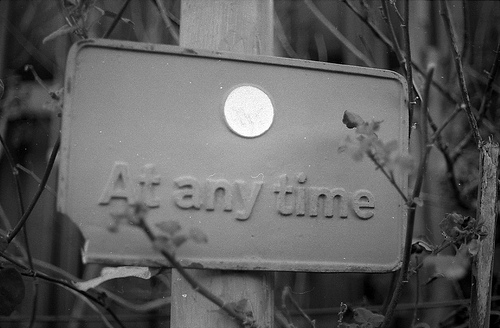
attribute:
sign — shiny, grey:
[62, 45, 448, 291]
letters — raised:
[107, 169, 422, 229]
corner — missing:
[53, 209, 88, 264]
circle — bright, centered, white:
[220, 84, 285, 143]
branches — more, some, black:
[373, 22, 493, 242]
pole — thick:
[181, 4, 287, 57]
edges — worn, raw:
[59, 37, 76, 130]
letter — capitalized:
[95, 162, 132, 221]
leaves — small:
[432, 214, 488, 245]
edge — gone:
[58, 225, 85, 270]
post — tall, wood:
[168, 1, 287, 308]